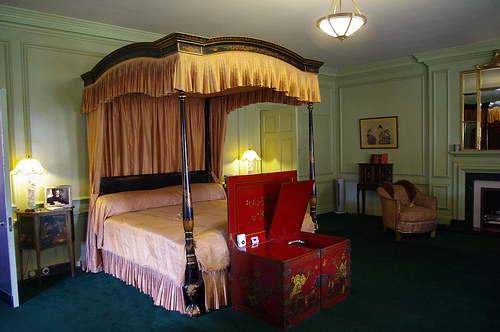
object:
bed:
[81, 179, 314, 307]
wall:
[317, 37, 499, 225]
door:
[258, 109, 297, 173]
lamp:
[10, 157, 45, 208]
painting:
[358, 118, 398, 149]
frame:
[47, 185, 74, 207]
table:
[19, 202, 76, 280]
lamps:
[12, 148, 260, 208]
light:
[317, 14, 370, 41]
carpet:
[1, 42, 497, 215]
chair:
[379, 179, 439, 238]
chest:
[223, 169, 359, 322]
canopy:
[89, 31, 320, 120]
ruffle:
[86, 60, 320, 113]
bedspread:
[101, 198, 231, 274]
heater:
[334, 177, 347, 214]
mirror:
[458, 86, 499, 157]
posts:
[179, 94, 203, 315]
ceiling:
[0, 3, 500, 68]